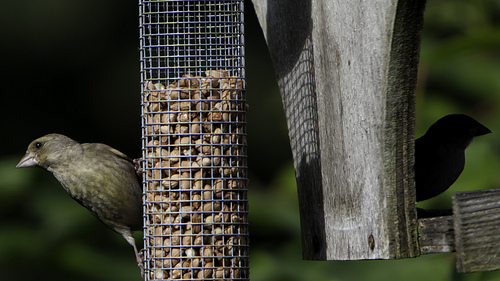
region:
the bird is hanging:
[6, 88, 156, 253]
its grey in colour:
[16, 96, 146, 260]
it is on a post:
[1, 90, 209, 271]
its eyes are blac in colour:
[34, 138, 46, 150]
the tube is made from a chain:
[137, 18, 255, 277]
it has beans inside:
[121, 43, 241, 279]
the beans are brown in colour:
[134, 68, 246, 257]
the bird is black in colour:
[416, 91, 484, 198]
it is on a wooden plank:
[286, 9, 498, 269]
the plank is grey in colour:
[268, 40, 390, 142]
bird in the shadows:
[409, 93, 496, 216]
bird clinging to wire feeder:
[19, 135, 142, 269]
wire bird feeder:
[136, 6, 248, 278]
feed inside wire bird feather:
[148, 67, 241, 274]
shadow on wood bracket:
[265, 8, 344, 266]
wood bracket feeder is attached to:
[251, 8, 491, 264]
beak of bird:
[12, 150, 33, 168]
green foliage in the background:
[2, 5, 489, 280]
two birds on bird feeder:
[7, 90, 498, 273]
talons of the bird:
[131, 146, 156, 279]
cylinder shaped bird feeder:
[136, 8, 245, 275]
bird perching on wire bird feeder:
[15, 126, 150, 269]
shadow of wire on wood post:
[267, 10, 319, 155]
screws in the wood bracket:
[306, 225, 383, 256]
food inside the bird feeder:
[150, 78, 240, 275]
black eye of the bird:
[32, 138, 42, 151]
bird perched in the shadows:
[415, 112, 492, 205]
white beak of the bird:
[17, 153, 38, 169]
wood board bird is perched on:
[412, 196, 499, 278]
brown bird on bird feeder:
[17, 131, 146, 278]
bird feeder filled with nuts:
[137, 0, 245, 279]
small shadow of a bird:
[411, 108, 493, 201]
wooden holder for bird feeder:
[252, 0, 497, 274]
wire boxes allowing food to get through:
[139, 8, 250, 279]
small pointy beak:
[12, 151, 37, 168]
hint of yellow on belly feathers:
[75, 159, 133, 202]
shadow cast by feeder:
[263, 2, 335, 262]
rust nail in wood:
[366, 231, 376, 250]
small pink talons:
[133, 246, 149, 273]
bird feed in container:
[148, 80, 246, 275]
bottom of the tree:
[264, 22, 411, 259]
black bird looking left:
[408, 109, 486, 189]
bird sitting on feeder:
[13, 130, 143, 256]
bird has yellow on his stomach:
[82, 165, 138, 231]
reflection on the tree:
[261, 38, 321, 261]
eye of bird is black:
[33, 139, 48, 154]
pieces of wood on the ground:
[417, 190, 495, 266]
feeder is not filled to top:
[137, 7, 244, 279]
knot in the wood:
[355, 215, 376, 265]